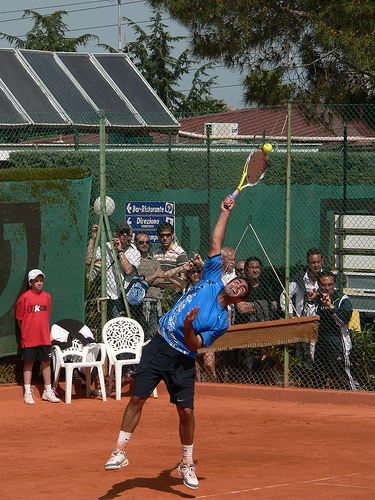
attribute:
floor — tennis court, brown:
[0, 363, 373, 497]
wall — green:
[6, 148, 373, 285]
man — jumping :
[99, 195, 247, 485]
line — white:
[255, 460, 362, 493]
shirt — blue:
[152, 252, 232, 357]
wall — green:
[7, 171, 365, 389]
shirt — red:
[10, 286, 68, 353]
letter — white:
[17, 294, 46, 320]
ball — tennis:
[261, 143, 272, 153]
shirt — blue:
[168, 251, 227, 353]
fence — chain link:
[93, 204, 357, 377]